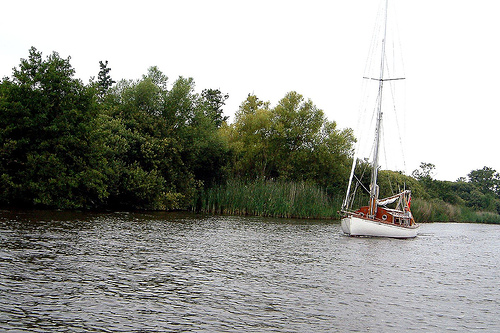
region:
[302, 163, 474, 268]
the boat is white in colour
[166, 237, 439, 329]
the water is calm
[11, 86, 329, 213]
trees are on the riverside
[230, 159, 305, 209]
the reeds are green in colour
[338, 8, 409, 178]
it has a large pole with no sail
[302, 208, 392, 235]
its front is pointed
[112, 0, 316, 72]
the sky is white in color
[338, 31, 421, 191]
its shaped like a cross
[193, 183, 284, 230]
the reeds have a brown base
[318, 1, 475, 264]
a sail boat on water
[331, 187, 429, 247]
a red and white sailboat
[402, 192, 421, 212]
a red flag on the back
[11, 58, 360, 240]
trees along the shore line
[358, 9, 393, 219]
large metal pole for mast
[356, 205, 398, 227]
two round windows on front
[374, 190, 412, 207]
white mast wrapped up on pole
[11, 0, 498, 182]
a clear white sky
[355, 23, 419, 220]
several wires come down from mast pole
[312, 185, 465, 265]
a boat in the water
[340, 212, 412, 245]
white hull of the boat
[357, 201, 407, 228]
red cabine of the boat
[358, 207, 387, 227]
round windows on boat's cabin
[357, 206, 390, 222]
white frames of windows on red cabin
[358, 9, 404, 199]
mast of red and white boat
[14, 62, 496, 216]
trees growing along the river bank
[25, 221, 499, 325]
ripples in the river water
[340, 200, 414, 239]
red and white boat traveling down the street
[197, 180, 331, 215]
tall grass growing in edge of river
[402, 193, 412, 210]
flag on back of the boat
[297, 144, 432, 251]
This is a sailboat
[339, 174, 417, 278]
The boat is white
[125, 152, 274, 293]
This is an old lake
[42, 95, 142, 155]
These are old trees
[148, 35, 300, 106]
The sky is very cloudy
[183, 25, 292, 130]
The sky is pure white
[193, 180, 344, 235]
These are tall weeds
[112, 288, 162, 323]
The lake is brown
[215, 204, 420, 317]
There are no people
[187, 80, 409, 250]
The sun is not shining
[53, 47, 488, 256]
a boat on the water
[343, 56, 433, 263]
this boat is red and white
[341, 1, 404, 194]
this boat has a long mast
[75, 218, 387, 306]
the water looks gray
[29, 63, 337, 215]
trees on the shore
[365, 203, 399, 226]
windows on the boat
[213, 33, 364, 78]
a gray sky above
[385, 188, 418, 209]
the back of the boat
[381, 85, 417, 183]
lines on the boat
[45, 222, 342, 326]
the water is wavey